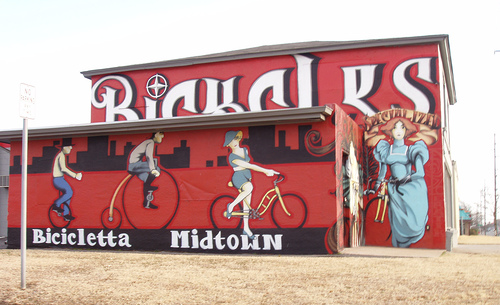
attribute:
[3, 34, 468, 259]
house — painted, red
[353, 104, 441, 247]
picture — a person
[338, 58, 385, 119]
letter — white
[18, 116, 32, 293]
pole — silver, grey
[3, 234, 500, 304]
grass — short, beige, brown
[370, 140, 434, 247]
dress — blue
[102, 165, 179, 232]
bike — crazy looking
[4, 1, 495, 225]
sky — white